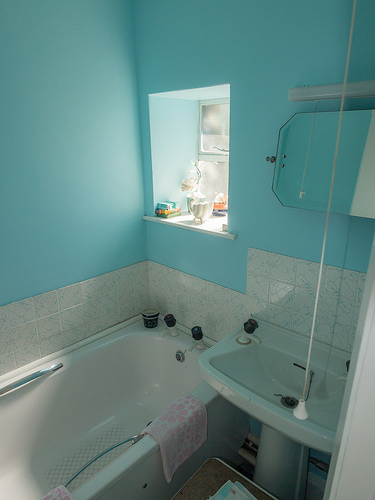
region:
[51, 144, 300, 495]
this is a bathroom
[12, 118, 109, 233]
the wall is bright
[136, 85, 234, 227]
this is a window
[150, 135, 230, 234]
the window is bright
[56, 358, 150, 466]
this is a bathtub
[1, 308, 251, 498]
Standard size white bathtub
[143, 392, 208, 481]
White towel with pink flowers on side of bathtub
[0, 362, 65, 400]
Silver handicap grab bar on side of bathtub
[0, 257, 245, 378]
White tile around bathtub has blue marble swirls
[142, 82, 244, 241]
Built-in shelving on window sill above tub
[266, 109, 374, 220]
Eight sided glass mirror above sink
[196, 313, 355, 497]
White pedestal sink near bathtub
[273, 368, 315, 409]
Sink drain plug attached with chain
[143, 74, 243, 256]
a small window in the wall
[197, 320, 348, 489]
a little white sink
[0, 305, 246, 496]
a tiny little white bath tub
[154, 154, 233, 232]
shampoos and bath toys on a window sill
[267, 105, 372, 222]
a mirror on a blue wall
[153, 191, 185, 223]
a little toy train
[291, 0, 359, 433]
a string for pulling blinds closed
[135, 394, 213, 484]
a washcloth on the side fo a tub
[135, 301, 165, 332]
a small bathtub candle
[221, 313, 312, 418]
white sink near tub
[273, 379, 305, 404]
drain is light grey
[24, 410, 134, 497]
white mat on tub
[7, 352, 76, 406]
silver bar on tub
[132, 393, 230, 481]
red and white towel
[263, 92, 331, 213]
blue cabinet over sink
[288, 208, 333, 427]
white cord near sink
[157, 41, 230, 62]
wall is light blue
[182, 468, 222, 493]
floor is light brown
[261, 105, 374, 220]
a mirror hanging on a wall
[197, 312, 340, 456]
a white bathroom sink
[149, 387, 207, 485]
a towel hanging over the side of a tub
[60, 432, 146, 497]
a silver handrail in a tub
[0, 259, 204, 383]
a tile wall around a tub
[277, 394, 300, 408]
a drain in a bathroom sink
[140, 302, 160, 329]
a cup on the side of a tub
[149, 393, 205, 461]
a pink and white towel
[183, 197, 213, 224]
a white glass bowl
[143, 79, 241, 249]
a small blue window hole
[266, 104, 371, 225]
a little mirror on a blue wall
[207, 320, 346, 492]
a short white sink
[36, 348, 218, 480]
a white bathtub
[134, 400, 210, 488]
a towel hanging from tub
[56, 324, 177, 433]
a white bathroom tub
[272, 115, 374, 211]
mirror above the sink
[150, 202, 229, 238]
ledge above the bathtub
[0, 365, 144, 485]
rails in the bathtub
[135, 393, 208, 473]
pink and white towel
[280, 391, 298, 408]
drain in the sink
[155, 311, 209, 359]
faucets on the bathtub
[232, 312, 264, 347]
faucet on the sink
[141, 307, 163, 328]
black cup on the bathtub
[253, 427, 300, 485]
stand the sink is on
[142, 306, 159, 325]
stacked cups by a tub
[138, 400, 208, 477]
a pink and white towel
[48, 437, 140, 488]
a rail by the tub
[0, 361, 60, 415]
a rail by the tub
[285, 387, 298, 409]
a stopper in a sink